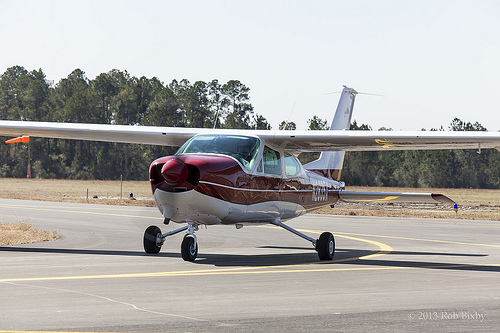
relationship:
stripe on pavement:
[1, 226, 499, 286] [2, 196, 499, 332]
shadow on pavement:
[0, 245, 500, 273] [2, 196, 499, 332]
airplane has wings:
[0, 85, 500, 261] [1, 118, 500, 150]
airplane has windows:
[0, 85, 500, 261] [173, 133, 304, 179]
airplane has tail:
[0, 85, 500, 261] [301, 84, 358, 188]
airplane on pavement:
[0, 85, 500, 261] [2, 196, 499, 332]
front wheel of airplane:
[180, 232, 200, 263] [0, 85, 500, 261]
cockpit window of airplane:
[176, 134, 260, 172] [0, 85, 500, 261]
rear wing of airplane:
[337, 190, 458, 204] [0, 85, 500, 261]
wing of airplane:
[260, 129, 499, 155] [0, 85, 500, 261]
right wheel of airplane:
[143, 224, 162, 256] [0, 85, 500, 261]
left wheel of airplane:
[317, 232, 335, 263] [0, 85, 500, 261]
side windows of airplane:
[256, 144, 305, 179] [0, 85, 500, 261]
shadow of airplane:
[0, 245, 500, 273] [0, 85, 500, 261]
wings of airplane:
[0, 118, 197, 148] [0, 85, 500, 261]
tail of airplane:
[301, 84, 358, 188] [0, 85, 500, 261]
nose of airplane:
[160, 159, 189, 184] [0, 85, 500, 261]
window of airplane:
[263, 144, 282, 175] [0, 85, 500, 261]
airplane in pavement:
[0, 85, 500, 261] [2, 196, 499, 332]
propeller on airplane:
[147, 139, 207, 209] [0, 85, 500, 261]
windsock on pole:
[5, 134, 32, 145] [26, 138, 31, 180]